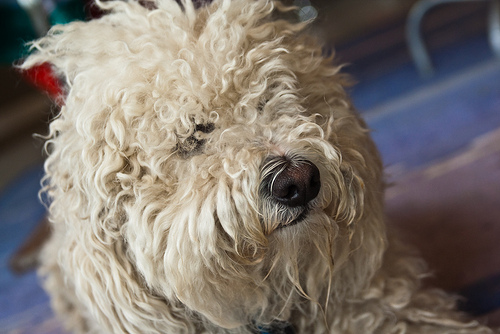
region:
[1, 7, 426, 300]
white dog in foreground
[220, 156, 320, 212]
black nose of white dog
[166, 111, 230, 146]
black eye on dog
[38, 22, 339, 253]
head of white dog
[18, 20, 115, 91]
curly fur of dog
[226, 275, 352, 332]
black piece of collar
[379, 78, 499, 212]
blue background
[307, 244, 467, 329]
leg of furry dog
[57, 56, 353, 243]
white dog looking forward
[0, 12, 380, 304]
furry white animal in foreground with black nose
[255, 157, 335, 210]
Nose of a dog.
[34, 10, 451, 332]
The dog has long hair.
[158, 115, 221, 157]
The eye under the hair.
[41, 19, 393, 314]
The hair is curly.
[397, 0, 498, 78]
The arm of the couch.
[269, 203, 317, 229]
The mouth is black.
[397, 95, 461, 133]
Blue on the carpet.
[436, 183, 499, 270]
Red on the rug.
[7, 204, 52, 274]
part of the wooden table.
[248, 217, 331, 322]
the hair is wet.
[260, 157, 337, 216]
black nose of a dog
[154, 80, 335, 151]
dog eyes almost hidden by fur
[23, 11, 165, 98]
crimped white fur of a dog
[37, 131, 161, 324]
white scraggly fur on a dog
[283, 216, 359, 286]
dirty wet fur by dog mouth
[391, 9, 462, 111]
metal table leg on carpet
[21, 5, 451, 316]
dog with white curly hair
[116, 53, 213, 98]
curly head hair of a dog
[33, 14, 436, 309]
white dog wagging its tail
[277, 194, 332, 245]
lips and mouth of dog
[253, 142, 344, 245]
small black nose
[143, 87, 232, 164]
hidden black eye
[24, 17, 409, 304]
furry white dog head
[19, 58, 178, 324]
furry floppy dog ear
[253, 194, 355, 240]
small mouth covered with fur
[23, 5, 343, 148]
white tuft of hair on dogs head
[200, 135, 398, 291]
hairy snout and mouth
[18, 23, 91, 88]
lone tuft of hair sticking up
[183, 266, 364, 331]
collar hidden by hair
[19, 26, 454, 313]
dog sitting blankly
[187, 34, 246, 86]
white curly fur of a dog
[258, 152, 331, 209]
a nose of a dog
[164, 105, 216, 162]
an eye of a dog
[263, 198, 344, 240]
a mouth of a dog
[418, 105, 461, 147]
a blue carpeting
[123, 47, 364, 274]
a face of a fuzzy dog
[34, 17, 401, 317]
the head of a dog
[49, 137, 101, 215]
the curly fur of a dog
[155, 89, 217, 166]
a fur covered eye of a dog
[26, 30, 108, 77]
the ear of a dog